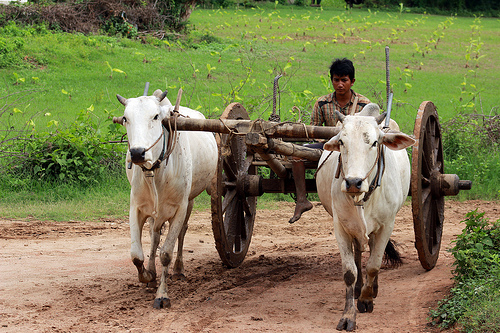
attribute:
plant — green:
[452, 69, 477, 105]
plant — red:
[456, 17, 482, 118]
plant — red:
[390, 15, 455, 99]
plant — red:
[265, 12, 399, 66]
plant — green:
[398, 82, 423, 98]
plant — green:
[402, 33, 427, 60]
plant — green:
[261, 55, 303, 77]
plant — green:
[453, 71, 481, 98]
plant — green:
[185, 55, 205, 91]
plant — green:
[102, 58, 125, 76]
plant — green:
[15, 77, 24, 87]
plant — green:
[29, 75, 39, 87]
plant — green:
[58, 83, 70, 100]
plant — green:
[82, 100, 97, 115]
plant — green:
[464, 45, 486, 55]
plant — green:
[20, 120, 125, 191]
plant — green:
[463, 52, 489, 73]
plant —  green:
[195, 55, 223, 83]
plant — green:
[100, 55, 130, 92]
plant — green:
[446, 189, 493, 314]